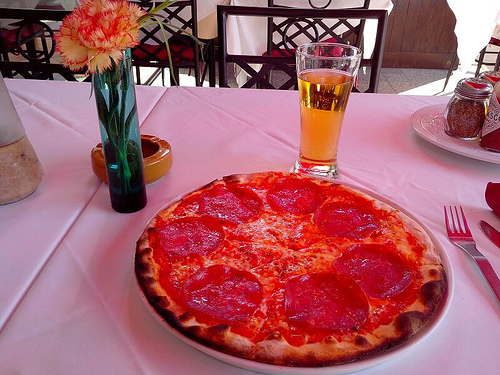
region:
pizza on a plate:
[140, 158, 457, 366]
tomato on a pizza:
[183, 261, 265, 316]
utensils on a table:
[432, 200, 497, 329]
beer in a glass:
[283, 31, 364, 178]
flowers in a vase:
[46, 1, 157, 221]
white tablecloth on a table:
[173, 86, 273, 159]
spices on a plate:
[403, 67, 496, 164]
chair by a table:
[210, 2, 390, 91]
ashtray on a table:
[87, 122, 179, 184]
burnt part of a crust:
[393, 311, 430, 337]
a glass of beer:
[296, 40, 363, 178]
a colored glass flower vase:
[89, 51, 148, 215]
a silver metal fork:
[444, 204, 499, 302]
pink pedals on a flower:
[55, 0, 148, 75]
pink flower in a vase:
[53, 0, 149, 215]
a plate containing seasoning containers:
[411, 70, 498, 167]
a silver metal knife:
[479, 220, 498, 248]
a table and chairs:
[0, 0, 396, 95]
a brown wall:
[329, 0, 460, 72]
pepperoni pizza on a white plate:
[131, 170, 454, 373]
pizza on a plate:
[127, 170, 452, 372]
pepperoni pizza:
[133, 176, 453, 357]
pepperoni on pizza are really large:
[160, 180, 395, 327]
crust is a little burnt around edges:
[131, 222, 438, 357]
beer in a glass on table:
[285, 41, 361, 176]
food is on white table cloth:
[21, 75, 491, 366]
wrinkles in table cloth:
[40, 75, 490, 370]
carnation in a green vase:
[60, 15, 162, 210]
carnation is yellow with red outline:
[50, 0, 137, 75]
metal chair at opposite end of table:
[202, 34, 389, 97]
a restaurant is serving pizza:
[17, 5, 499, 362]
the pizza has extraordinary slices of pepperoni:
[133, 169, 450, 367]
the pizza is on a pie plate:
[135, 164, 457, 371]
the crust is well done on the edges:
[130, 253, 220, 353]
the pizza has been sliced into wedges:
[142, 174, 444, 359]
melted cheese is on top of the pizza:
[170, 185, 415, 355]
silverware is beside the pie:
[436, 200, 498, 308]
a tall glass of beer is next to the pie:
[286, 37, 360, 217]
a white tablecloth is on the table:
[12, 75, 499, 372]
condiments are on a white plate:
[415, 68, 499, 161]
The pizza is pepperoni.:
[130, 170, 450, 370]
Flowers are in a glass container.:
[51, 0, 158, 215]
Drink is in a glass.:
[291, 34, 363, 179]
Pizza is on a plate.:
[132, 168, 450, 369]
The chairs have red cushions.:
[0, 0, 386, 100]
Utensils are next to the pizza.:
[438, 172, 498, 308]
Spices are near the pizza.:
[446, 62, 499, 155]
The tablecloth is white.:
[0, 78, 499, 373]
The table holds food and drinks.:
[0, 77, 499, 372]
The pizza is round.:
[134, 170, 454, 372]